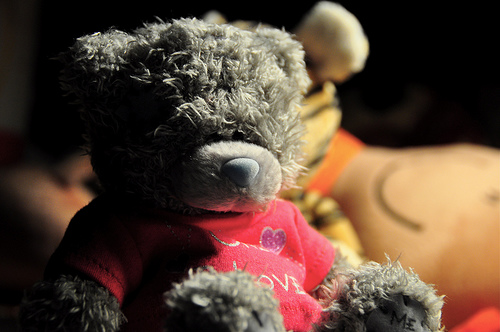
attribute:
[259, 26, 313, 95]
ear — gray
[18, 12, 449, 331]
bear — gray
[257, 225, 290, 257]
heart — light pink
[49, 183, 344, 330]
shirt — red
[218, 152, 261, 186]
nose — grey, gray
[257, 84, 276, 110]
eyes — small, black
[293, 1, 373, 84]
ear — white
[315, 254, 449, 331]
paw — brown